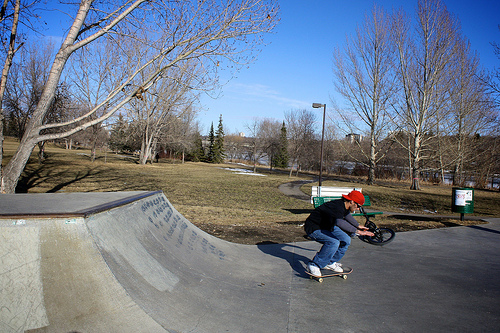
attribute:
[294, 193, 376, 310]
man — trying to balance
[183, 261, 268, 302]
concrete — gray, for skateboards, ramp, at skate park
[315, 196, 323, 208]
bench — green, black, at skate park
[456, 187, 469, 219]
trash can — green, at skate park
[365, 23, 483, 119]
trees — tall, bare, grouped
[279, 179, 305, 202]
path — gray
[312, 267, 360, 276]
skateboard — on ramp, black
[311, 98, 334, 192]
light — tall, black